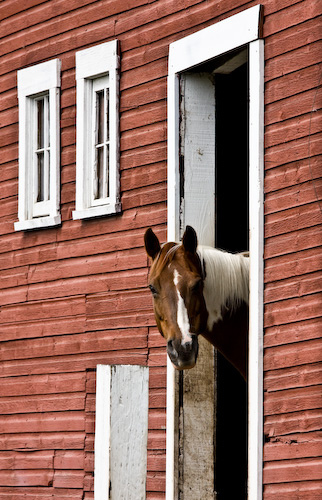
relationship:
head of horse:
[135, 219, 213, 373] [139, 217, 258, 393]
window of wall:
[19, 87, 64, 223] [2, 0, 321, 499]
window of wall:
[81, 68, 117, 207] [2, 0, 321, 499]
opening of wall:
[163, 39, 259, 500] [2, 0, 321, 499]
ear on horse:
[140, 220, 163, 262] [139, 217, 258, 393]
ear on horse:
[178, 223, 201, 260] [139, 217, 258, 393]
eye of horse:
[147, 282, 164, 302] [139, 217, 258, 393]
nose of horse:
[171, 336, 194, 357] [139, 217, 258, 393]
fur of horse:
[189, 234, 256, 335] [139, 217, 258, 393]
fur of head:
[189, 234, 256, 335] [135, 219, 213, 373]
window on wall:
[19, 87, 64, 223] [2, 0, 321, 499]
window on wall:
[81, 68, 117, 207] [2, 0, 321, 499]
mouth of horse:
[168, 353, 201, 371] [139, 217, 258, 393]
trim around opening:
[159, 4, 271, 500] [163, 39, 259, 500]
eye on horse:
[147, 282, 164, 302] [139, 217, 258, 393]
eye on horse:
[189, 281, 202, 296] [139, 217, 258, 393]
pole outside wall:
[91, 359, 149, 500] [2, 0, 321, 499]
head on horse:
[135, 219, 213, 373] [139, 217, 258, 393]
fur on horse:
[189, 234, 256, 335] [139, 217, 258, 393]